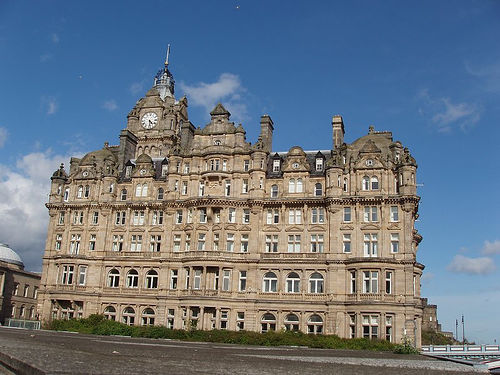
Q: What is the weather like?
A: It is cloudy.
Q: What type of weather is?
A: It is cloudy.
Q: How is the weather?
A: It is cloudy.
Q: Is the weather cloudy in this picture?
A: Yes, it is cloudy.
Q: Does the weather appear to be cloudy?
A: Yes, it is cloudy.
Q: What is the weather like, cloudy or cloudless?
A: It is cloudy.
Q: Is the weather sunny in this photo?
A: No, it is cloudy.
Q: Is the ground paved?
A: Yes, the ground is paved.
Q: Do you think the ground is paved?
A: Yes, the ground is paved.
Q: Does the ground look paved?
A: Yes, the ground is paved.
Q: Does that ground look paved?
A: Yes, the ground is paved.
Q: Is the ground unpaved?
A: No, the ground is paved.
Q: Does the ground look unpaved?
A: No, the ground is paved.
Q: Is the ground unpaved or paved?
A: The ground is paved.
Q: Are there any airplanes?
A: No, there are no airplanes.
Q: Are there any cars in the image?
A: No, there are no cars.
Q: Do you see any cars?
A: No, there are no cars.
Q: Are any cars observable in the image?
A: No, there are no cars.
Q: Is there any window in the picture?
A: Yes, there are windows.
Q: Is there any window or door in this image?
A: Yes, there are windows.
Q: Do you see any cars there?
A: No, there are no cars.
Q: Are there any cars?
A: No, there are no cars.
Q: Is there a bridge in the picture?
A: Yes, there is a bridge.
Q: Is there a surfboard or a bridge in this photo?
A: Yes, there is a bridge.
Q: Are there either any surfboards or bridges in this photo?
A: Yes, there is a bridge.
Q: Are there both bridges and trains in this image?
A: No, there is a bridge but no trains.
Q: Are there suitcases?
A: No, there are no suitcases.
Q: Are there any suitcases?
A: No, there are no suitcases.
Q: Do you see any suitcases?
A: No, there are no suitcases.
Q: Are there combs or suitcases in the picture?
A: No, there are no suitcases or combs.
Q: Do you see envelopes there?
A: No, there are no envelopes.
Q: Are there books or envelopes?
A: No, there are no envelopes or books.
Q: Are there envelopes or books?
A: No, there are no envelopes or books.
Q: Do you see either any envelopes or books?
A: No, there are no envelopes or books.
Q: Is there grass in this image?
A: Yes, there is grass.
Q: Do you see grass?
A: Yes, there is grass.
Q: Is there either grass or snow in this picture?
A: Yes, there is grass.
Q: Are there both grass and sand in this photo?
A: No, there is grass but no sand.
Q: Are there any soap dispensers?
A: No, there are no soap dispensers.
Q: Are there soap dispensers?
A: No, there are no soap dispensers.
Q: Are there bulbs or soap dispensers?
A: No, there are no soap dispensers or bulbs.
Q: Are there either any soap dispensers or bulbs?
A: No, there are no soap dispensers or bulbs.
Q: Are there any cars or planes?
A: No, there are no cars or planes.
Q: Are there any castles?
A: Yes, there is a castle.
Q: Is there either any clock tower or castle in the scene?
A: Yes, there is a castle.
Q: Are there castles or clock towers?
A: Yes, there is a castle.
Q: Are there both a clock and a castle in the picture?
A: Yes, there are both a castle and a clock.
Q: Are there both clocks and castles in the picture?
A: Yes, there are both a castle and a clock.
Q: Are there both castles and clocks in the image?
A: Yes, there are both a castle and a clock.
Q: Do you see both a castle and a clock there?
A: Yes, there are both a castle and a clock.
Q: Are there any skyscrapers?
A: No, there are no skyscrapers.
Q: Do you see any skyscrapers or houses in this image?
A: No, there are no skyscrapers or houses.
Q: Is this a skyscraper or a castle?
A: This is a castle.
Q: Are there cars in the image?
A: No, there are no cars.